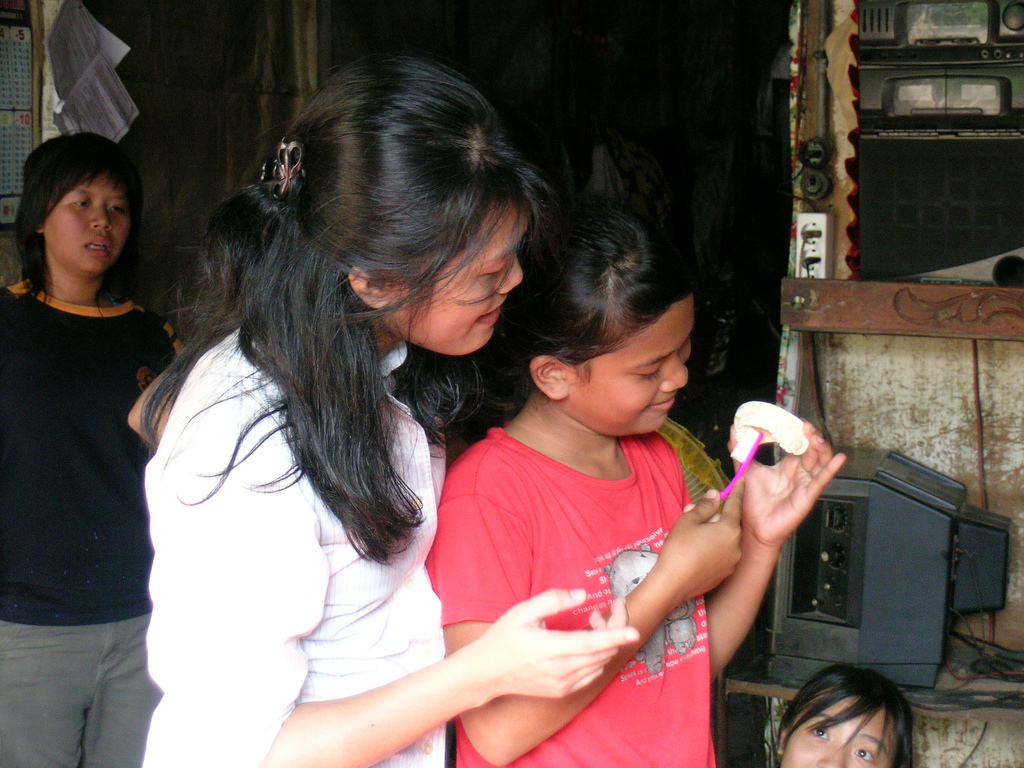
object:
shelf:
[780, 274, 1023, 344]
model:
[733, 401, 810, 457]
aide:
[423, 210, 848, 767]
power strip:
[796, 213, 835, 281]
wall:
[785, 336, 1024, 463]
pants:
[2, 612, 165, 768]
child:
[425, 206, 850, 764]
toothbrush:
[719, 427, 764, 502]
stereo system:
[857, 0, 1024, 288]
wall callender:
[2, 23, 45, 226]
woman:
[5, 130, 192, 764]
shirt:
[2, 282, 190, 627]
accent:
[136, 365, 157, 392]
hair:
[137, 51, 558, 570]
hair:
[777, 663, 916, 766]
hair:
[452, 203, 701, 447]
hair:
[16, 131, 144, 305]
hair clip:
[258, 134, 307, 203]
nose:
[659, 354, 688, 393]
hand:
[659, 476, 748, 601]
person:
[423, 203, 846, 762]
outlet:
[798, 137, 835, 169]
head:
[258, 53, 532, 357]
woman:
[102, 39, 649, 763]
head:
[520, 207, 696, 438]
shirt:
[139, 325, 450, 766]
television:
[750, 451, 1015, 691]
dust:
[785, 619, 865, 659]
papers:
[55, 52, 140, 144]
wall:
[2, 1, 568, 397]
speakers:
[855, 135, 1024, 284]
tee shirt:
[427, 424, 720, 764]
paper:
[46, 5, 134, 114]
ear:
[526, 354, 575, 402]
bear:
[603, 542, 698, 675]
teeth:
[734, 400, 810, 456]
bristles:
[729, 428, 758, 464]